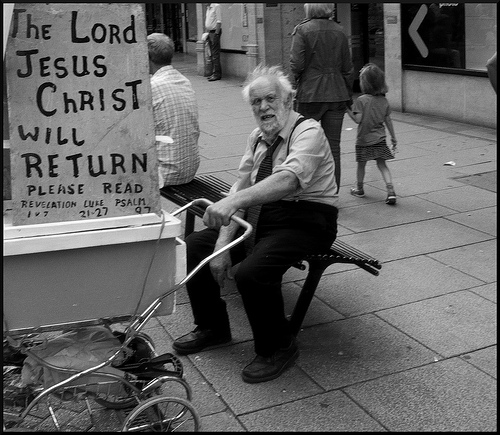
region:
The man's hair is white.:
[233, 60, 318, 106]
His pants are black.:
[182, 212, 349, 352]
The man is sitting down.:
[192, 67, 349, 392]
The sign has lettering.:
[0, 9, 177, 216]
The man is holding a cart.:
[22, 193, 261, 424]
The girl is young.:
[343, 60, 400, 202]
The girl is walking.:
[353, 63, 406, 213]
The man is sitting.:
[143, 32, 207, 190]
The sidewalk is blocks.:
[182, 71, 499, 428]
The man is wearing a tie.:
[248, 138, 281, 188]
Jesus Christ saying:
[4, 6, 166, 225]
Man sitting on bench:
[186, 62, 356, 390]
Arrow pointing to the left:
[404, 6, 440, 74]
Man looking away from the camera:
[147, 21, 209, 191]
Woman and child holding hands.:
[277, 2, 417, 216]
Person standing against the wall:
[204, 0, 238, 87]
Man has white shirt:
[186, 63, 353, 372]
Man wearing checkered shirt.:
[144, 21, 215, 204]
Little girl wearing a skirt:
[353, 48, 418, 208]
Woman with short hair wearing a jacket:
[285, 3, 353, 114]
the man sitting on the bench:
[172, 62, 339, 383]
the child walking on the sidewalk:
[346, 63, 396, 205]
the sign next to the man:
[7, 1, 161, 225]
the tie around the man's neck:
[241, 137, 279, 256]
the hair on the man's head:
[240, 62, 296, 108]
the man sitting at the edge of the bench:
[146, 31, 199, 188]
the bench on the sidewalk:
[158, 174, 380, 334]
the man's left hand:
[202, 197, 236, 228]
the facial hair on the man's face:
[251, 99, 289, 136]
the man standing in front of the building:
[204, 2, 222, 82]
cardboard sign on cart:
[3, 4, 180, 222]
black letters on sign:
[2, 7, 172, 229]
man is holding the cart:
[169, 49, 351, 399]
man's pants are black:
[163, 196, 356, 383]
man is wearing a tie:
[242, 135, 288, 182]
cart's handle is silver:
[5, 189, 262, 432]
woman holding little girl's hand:
[282, 3, 420, 199]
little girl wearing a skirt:
[333, 126, 401, 170]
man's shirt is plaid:
[141, 70, 216, 185]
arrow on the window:
[398, 5, 433, 67]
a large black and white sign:
[2, 0, 165, 220]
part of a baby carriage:
[5, 198, 251, 433]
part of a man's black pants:
[182, 199, 339, 356]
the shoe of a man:
[235, 348, 305, 383]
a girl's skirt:
[354, 138, 393, 162]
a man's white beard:
[250, 100, 297, 137]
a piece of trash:
[440, 155, 462, 166]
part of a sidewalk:
[154, 47, 497, 434]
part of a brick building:
[400, 68, 497, 126]